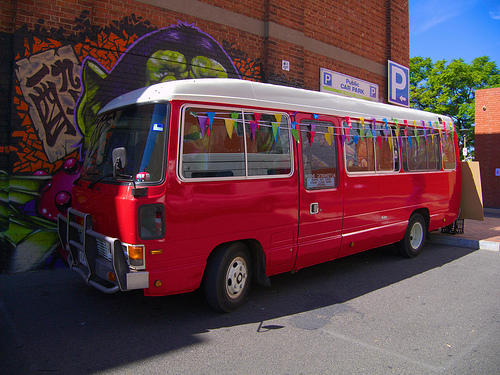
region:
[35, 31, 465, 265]
picture taken outdoors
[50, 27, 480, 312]
picture taken during the day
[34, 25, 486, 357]
a red bus next to a building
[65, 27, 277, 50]
the building has graffiti on it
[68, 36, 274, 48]
the building is made of brick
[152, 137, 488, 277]
the bus is red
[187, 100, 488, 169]
the bus has flags on the top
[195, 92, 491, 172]
the top of the bus is white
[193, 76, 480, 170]
the flags are varied in color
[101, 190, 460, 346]
the bus is not moving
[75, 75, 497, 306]
A mini van parked above the road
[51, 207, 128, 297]
Silver color chrome bumber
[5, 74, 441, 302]
A red and white color mini van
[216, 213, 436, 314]
Black and silver color wheels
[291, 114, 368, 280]
Main door of the mini van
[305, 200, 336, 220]
Handle of the main door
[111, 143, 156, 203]
Side mirror of the mini van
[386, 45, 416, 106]
Parking signal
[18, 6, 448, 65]
Building near the road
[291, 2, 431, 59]
A red color bricks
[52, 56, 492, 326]
red painted bus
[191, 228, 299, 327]
black tire of bus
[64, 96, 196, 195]
windshield of red bus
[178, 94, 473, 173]
colorful flags hung on bus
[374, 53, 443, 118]
a parking direction sign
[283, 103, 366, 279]
door to red bus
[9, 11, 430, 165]
brick building with painted mural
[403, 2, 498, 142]
blue sky and green tree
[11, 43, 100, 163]
asian writing on mural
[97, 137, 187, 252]
headlight and rear view mirror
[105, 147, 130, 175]
MIRROR HANGING OFF THE SIDE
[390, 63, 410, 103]
BLUE SIGN WITH A WHITE P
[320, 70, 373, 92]
PUBLIC CAR PARKING SIGN ON BUILDING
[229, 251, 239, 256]
TIRE ON THE BUS ARE BLACK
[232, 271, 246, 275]
RIM INSIDE THE TIRE IS WHITE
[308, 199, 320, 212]
HANDLE ON THE BUS IS WHITE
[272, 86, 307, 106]
ROOF OF THE BUS IS WHITE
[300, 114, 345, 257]
DOOR IS ON THE SIDE OF THE BUS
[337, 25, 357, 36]
BUILDING IS MAE OUT OF ORANGE BRICKS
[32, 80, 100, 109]
GRAFFITI ON THE WALL OF THE BUILDING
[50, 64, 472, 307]
Bright red and white combi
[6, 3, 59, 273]
Multi-colored graffiti on brick wall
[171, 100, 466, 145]
Multi-colored triangular flags hung on vehicle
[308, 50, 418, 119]
Signs on wall indicating parking area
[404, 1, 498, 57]
Clear bright blue skies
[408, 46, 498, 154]
Bright green tree behind building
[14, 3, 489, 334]
Combi parked in front of brick building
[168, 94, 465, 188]
Row of windows with white frames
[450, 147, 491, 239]
Brown board leaning against combi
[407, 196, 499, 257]
Pink sidewalk behind parking area